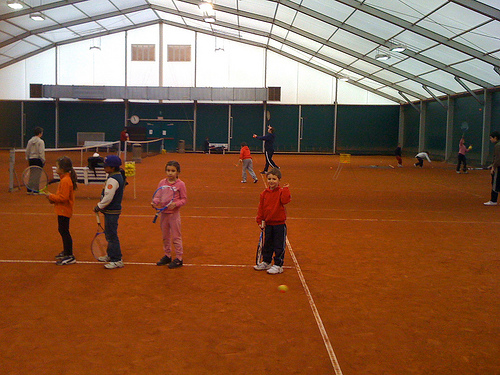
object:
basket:
[123, 160, 137, 200]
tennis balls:
[129, 172, 133, 174]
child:
[412, 150, 433, 169]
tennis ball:
[275, 282, 292, 292]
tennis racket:
[146, 179, 180, 222]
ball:
[273, 279, 289, 294]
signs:
[166, 43, 191, 61]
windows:
[0, 44, 58, 100]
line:
[297, 276, 317, 307]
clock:
[129, 115, 139, 125]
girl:
[138, 152, 197, 281]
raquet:
[148, 176, 171, 223]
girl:
[137, 154, 201, 269]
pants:
[147, 210, 194, 262]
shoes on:
[265, 265, 283, 274]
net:
[121, 135, 167, 166]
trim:
[124, 134, 162, 147]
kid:
[233, 138, 257, 184]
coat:
[253, 187, 291, 224]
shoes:
[253, 262, 274, 270]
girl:
[151, 160, 188, 268]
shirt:
[151, 175, 186, 212]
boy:
[252, 170, 291, 273]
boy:
[255, 166, 290, 275]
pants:
[263, 222, 285, 264]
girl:
[35, 153, 85, 268]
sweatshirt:
[38, 173, 83, 218]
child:
[251, 170, 293, 277]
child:
[151, 159, 188, 267]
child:
[94, 156, 128, 269]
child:
[38, 158, 75, 264]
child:
[235, 141, 257, 184]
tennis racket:
[255, 219, 263, 264]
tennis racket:
[150, 184, 176, 226]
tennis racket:
[90, 208, 107, 263]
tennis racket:
[20, 164, 50, 195]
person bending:
[413, 152, 435, 169]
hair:
[262, 164, 282, 184]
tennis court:
[0, 150, 500, 374]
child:
[394, 141, 406, 168]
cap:
[99, 157, 122, 166]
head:
[99, 154, 121, 176]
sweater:
[252, 187, 292, 229]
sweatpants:
[257, 222, 289, 266]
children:
[235, 138, 256, 182]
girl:
[147, 155, 194, 272]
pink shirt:
[152, 176, 189, 243]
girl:
[148, 159, 199, 272]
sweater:
[150, 175, 188, 212]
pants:
[159, 212, 183, 260]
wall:
[1, 102, 406, 152]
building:
[0, 0, 497, 372]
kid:
[256, 170, 292, 276]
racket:
[256, 220, 265, 263]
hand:
[256, 214, 266, 229]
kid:
[413, 146, 427, 168]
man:
[251, 109, 288, 175]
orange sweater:
[46, 172, 77, 218]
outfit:
[149, 170, 189, 258]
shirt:
[256, 178, 292, 224]